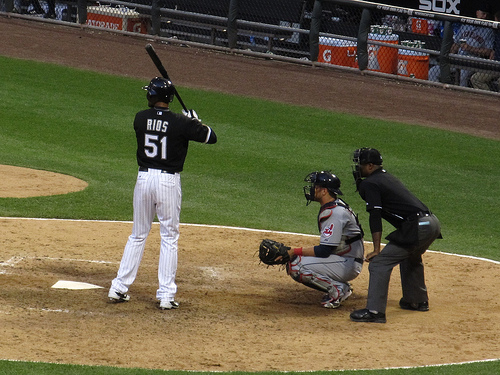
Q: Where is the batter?
A: In batter's box.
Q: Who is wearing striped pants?
A: The batter.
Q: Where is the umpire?
A: Behind the catcher.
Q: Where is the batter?
A: At the plate.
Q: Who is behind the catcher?
A: Umpire.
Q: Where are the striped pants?
A: On player.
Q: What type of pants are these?
A: White.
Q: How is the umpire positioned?
A: Bent over.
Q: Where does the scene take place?
A: At a baseball game.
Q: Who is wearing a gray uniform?
A: Catcher.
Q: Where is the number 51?
A: On back of batter's uniform.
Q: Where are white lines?
A: On the dirt.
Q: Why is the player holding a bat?
A: To hit the ball.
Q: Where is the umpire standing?
A: Behind the catcher.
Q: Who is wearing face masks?
A: Catcher and umpire.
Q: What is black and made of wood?
A: Baseball bat.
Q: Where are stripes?
A: On batter's pants.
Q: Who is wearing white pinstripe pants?
A: The batter.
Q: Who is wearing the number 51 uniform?
A: The batter.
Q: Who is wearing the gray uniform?
A: The catcher.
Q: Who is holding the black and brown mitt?
A: The catcher.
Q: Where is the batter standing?
A: At home plate.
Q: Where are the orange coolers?
A: Behind the fence.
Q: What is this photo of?
A: People playing a sport.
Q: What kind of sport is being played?
A: Baseball.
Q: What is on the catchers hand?
A: A catchers mitt.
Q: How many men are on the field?
A: Three.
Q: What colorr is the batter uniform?
A: Black and White.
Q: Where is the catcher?
A: Behind the batter.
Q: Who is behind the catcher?
A: The umpire.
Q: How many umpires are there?
A: One.